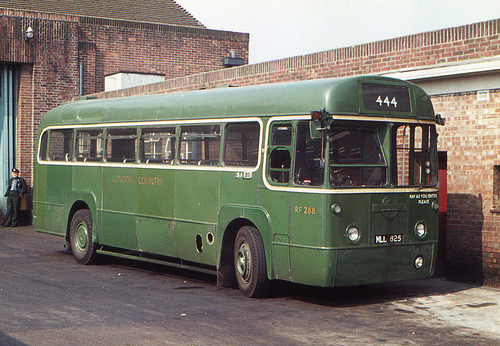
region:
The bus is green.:
[22, 68, 452, 308]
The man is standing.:
[0, 156, 32, 233]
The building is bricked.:
[1, 4, 255, 261]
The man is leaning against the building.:
[0, 5, 258, 258]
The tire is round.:
[56, 199, 113, 271]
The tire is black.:
[53, 193, 108, 272]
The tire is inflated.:
[53, 199, 109, 268]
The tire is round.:
[223, 219, 279, 306]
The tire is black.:
[225, 210, 282, 305]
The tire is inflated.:
[213, 208, 278, 305]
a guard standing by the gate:
[3, 163, 25, 223]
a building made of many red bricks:
[6, 3, 249, 168]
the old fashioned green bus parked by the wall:
[30, 73, 442, 304]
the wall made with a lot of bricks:
[238, 17, 499, 270]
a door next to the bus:
[406, 150, 452, 272]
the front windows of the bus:
[333, 126, 434, 180]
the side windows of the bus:
[36, 114, 266, 176]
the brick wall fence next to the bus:
[258, 24, 498, 274]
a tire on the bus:
[225, 230, 267, 295]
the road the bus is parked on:
[0, 230, 498, 344]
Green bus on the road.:
[37, 73, 440, 297]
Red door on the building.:
[406, 146, 451, 281]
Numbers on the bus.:
[372, 91, 401, 108]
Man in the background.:
[4, 165, 26, 225]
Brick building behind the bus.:
[0, 0, 497, 281]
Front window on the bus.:
[264, 113, 439, 195]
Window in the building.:
[489, 163, 499, 215]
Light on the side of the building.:
[22, 23, 35, 40]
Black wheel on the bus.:
[230, 222, 267, 299]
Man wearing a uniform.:
[5, 167, 25, 226]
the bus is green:
[171, 201, 206, 228]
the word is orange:
[291, 200, 319, 220]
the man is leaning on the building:
[3, 159, 29, 196]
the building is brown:
[40, 49, 65, 80]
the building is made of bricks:
[41, 55, 66, 92]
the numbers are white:
[371, 88, 401, 111]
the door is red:
[429, 164, 451, 211]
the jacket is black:
[16, 176, 26, 196]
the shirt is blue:
[8, 178, 18, 189]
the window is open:
[268, 142, 298, 182]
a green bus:
[33, 72, 439, 297]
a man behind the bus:
[1, 165, 26, 226]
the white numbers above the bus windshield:
[375, 92, 396, 104]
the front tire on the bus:
[232, 225, 262, 295]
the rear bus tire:
[67, 206, 97, 261]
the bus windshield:
[327, 121, 429, 186]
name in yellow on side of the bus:
[110, 170, 165, 182]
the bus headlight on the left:
[340, 221, 360, 241]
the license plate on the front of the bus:
[370, 231, 401, 241]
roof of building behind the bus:
[0, 0, 206, 26]